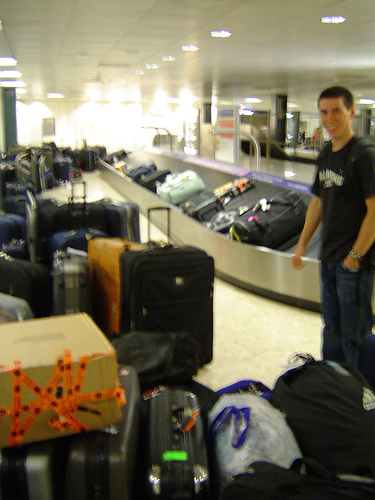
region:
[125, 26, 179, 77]
part of a ceiling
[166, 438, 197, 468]
part of a case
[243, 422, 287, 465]
part of a paper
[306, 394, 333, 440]
part of a trouser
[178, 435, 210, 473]
edge of a bag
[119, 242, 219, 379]
this is a suit case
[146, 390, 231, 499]
this is a suit case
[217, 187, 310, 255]
this is a suit case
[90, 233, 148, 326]
this is a suit case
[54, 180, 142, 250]
this is a suit case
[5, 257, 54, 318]
this is a suit case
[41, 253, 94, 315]
this is a suit case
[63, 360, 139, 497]
this is a suit case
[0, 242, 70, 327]
luggage in airport baggage claim area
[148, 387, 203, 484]
luggage in airport baggage claim area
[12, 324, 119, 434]
luggage in airport baggage claim area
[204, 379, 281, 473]
luggage in airport baggage claim area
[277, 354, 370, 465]
luggage in airport baggage claim area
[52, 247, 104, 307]
luggage in airport baggage claim area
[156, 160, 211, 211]
luggage in airport baggage claim area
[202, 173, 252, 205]
luggage in airport baggage claim area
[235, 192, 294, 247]
luggage in airport baggage claim area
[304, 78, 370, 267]
young man standing in baggage area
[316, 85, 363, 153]
Younger man smiling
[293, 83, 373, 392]
Smile on a young man's face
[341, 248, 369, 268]
Wrist watch on man's left hand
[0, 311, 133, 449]
Package with criss crossed orange tape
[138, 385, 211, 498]
Black luggage with green tag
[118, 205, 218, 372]
Large black luggage in front of orange luggage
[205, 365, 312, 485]
White bag with blue handles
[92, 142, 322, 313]
Conveyor belt pushing luggages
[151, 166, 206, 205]
Green luggage on conveyor belt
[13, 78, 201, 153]
Bright sun reflection in airport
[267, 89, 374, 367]
Young man standing wearing a dark t shirt with white writing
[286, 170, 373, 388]
Young man wearing dark blue jeans with his hand in his pocket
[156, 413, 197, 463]
Green tag on the top of a black suitcase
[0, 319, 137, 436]
Light tan package with numerous orange stickers across the side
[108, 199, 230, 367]
Black suitcase standing upright with a gold piece on the front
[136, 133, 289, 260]
Carousel taking luggage around in a circle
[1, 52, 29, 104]
Row of bright lights built into a white ceiling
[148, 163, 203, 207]
Light blue suitcase laying on the luggage carousel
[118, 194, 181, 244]
Extended black handle of a piece of luggage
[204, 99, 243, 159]
White sign with orange and blue portions